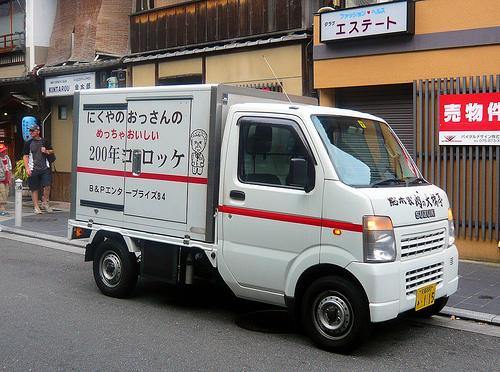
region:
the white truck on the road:
[64, 85, 457, 347]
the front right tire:
[304, 284, 368, 351]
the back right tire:
[92, 239, 135, 296]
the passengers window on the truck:
[235, 123, 312, 184]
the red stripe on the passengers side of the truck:
[215, 201, 365, 228]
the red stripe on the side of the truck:
[75, 162, 210, 184]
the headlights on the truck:
[363, 208, 455, 262]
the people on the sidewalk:
[0, 123, 55, 218]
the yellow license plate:
[414, 280, 436, 310]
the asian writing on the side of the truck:
[77, 100, 206, 218]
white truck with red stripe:
[64, 85, 465, 325]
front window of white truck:
[317, 110, 417, 192]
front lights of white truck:
[371, 198, 456, 263]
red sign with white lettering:
[435, 93, 498, 148]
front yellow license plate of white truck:
[412, 281, 438, 310]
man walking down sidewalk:
[17, 123, 54, 215]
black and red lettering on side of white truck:
[79, 104, 186, 206]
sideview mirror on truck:
[282, 155, 309, 185]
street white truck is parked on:
[1, 230, 499, 366]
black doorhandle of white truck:
[225, 186, 249, 205]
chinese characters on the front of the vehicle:
[379, 191, 452, 211]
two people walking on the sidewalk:
[0, 118, 65, 215]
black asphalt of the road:
[3, 295, 222, 364]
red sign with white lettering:
[441, 95, 498, 125]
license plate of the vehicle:
[408, 282, 440, 309]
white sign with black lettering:
[38, 75, 97, 90]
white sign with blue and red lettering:
[313, 5, 410, 34]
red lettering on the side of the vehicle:
[89, 125, 170, 144]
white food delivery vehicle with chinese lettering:
[72, 84, 454, 344]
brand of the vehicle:
[404, 207, 444, 222]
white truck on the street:
[59, 90, 460, 345]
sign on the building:
[317, 3, 413, 39]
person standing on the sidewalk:
[21, 118, 55, 214]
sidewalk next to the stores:
[0, 196, 497, 328]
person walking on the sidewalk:
[0, 141, 10, 213]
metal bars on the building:
[410, 71, 499, 247]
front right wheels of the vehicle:
[296, 268, 364, 350]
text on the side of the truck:
[82, 96, 187, 223]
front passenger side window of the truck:
[235, 116, 318, 196]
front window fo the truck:
[304, 113, 422, 188]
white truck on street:
[63, 83, 463, 349]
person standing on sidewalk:
[17, 122, 54, 212]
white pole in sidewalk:
[10, 176, 20, 221]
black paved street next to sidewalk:
[1, 225, 496, 366]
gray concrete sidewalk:
[0, 195, 495, 320]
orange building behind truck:
[310, 5, 495, 261]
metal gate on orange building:
[412, 71, 497, 238]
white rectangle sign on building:
[320, 2, 412, 42]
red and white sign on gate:
[435, 86, 495, 146]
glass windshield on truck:
[310, 112, 435, 183]